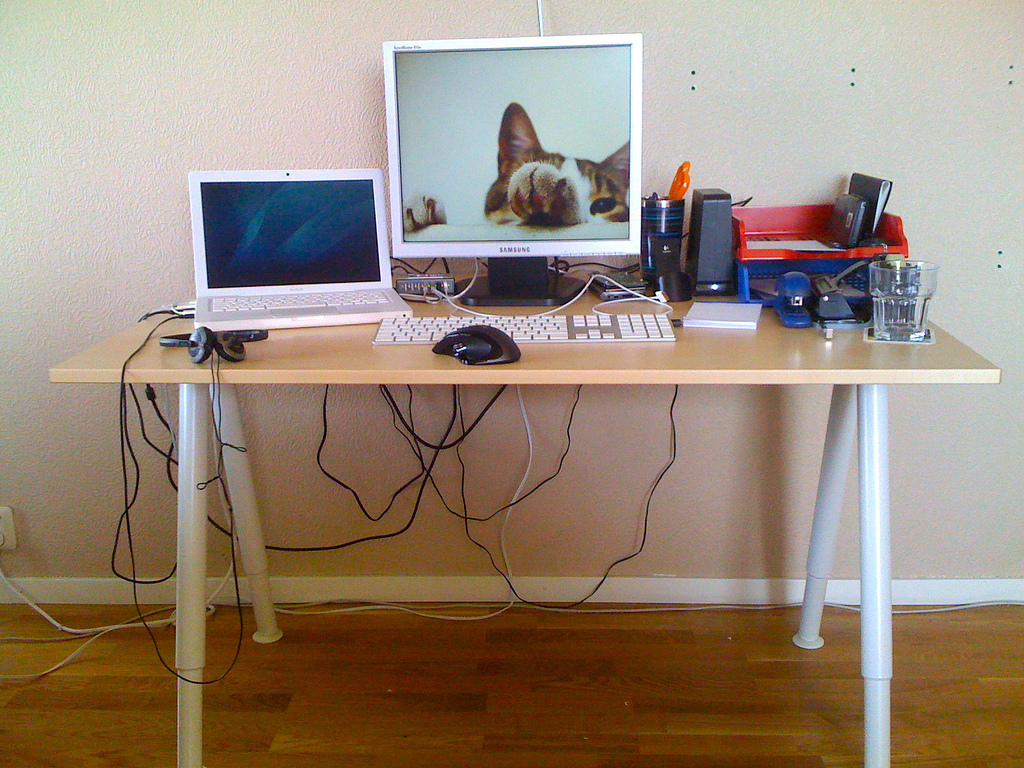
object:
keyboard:
[370, 310, 680, 349]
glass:
[866, 253, 942, 348]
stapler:
[772, 271, 814, 328]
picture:
[392, 43, 631, 245]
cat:
[402, 99, 634, 233]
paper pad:
[682, 300, 763, 330]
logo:
[496, 244, 532, 255]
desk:
[46, 287, 1016, 767]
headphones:
[155, 320, 269, 391]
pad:
[683, 299, 764, 329]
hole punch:
[811, 255, 879, 328]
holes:
[688, 84, 701, 93]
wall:
[657, 12, 772, 149]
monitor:
[379, 31, 650, 259]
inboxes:
[730, 194, 910, 310]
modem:
[395, 270, 456, 296]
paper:
[689, 306, 755, 326]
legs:
[166, 381, 216, 767]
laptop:
[184, 166, 414, 330]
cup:
[641, 195, 686, 275]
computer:
[377, 32, 680, 344]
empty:
[876, 263, 929, 336]